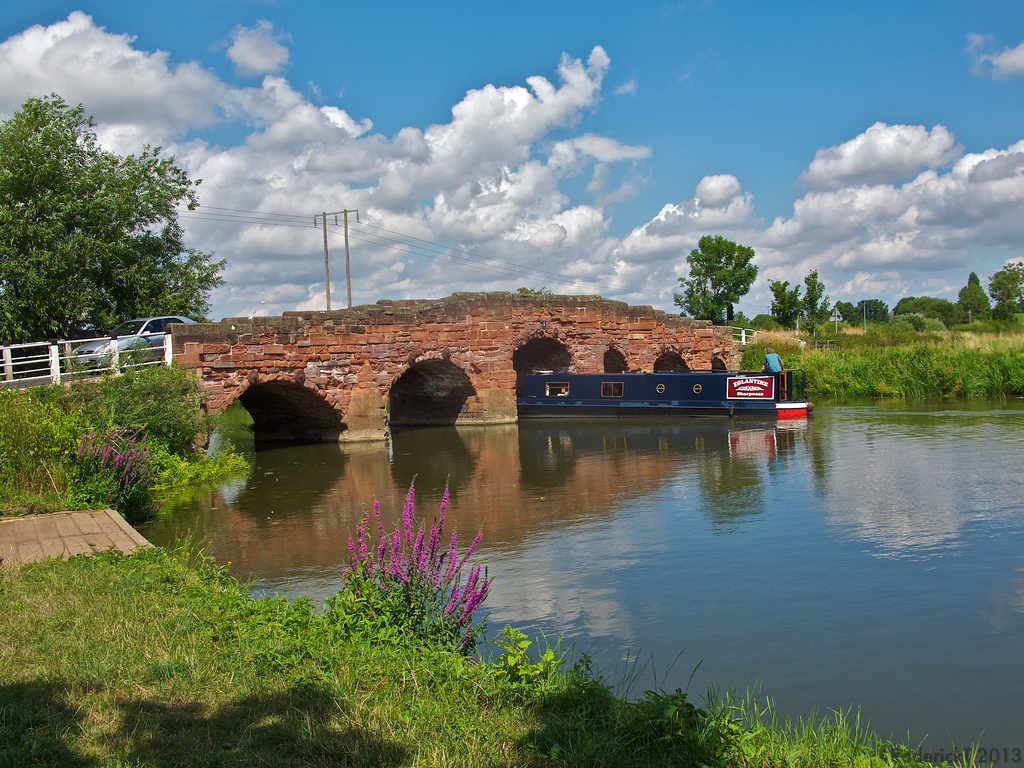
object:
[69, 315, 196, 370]
car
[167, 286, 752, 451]
bridge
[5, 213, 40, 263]
green tree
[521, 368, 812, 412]
boat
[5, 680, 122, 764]
grass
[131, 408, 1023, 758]
river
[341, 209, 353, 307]
telephone poles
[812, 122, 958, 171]
white clouds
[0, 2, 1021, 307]
blue sky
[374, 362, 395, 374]
rocks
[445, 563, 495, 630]
purple plants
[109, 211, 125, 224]
green leaves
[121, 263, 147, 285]
green leaves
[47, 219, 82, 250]
green leaves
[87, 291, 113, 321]
green leaves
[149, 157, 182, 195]
green leaves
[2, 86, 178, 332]
tree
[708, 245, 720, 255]
green leaves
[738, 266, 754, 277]
green leaves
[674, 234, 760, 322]
tree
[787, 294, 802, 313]
green leaves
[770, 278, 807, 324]
tree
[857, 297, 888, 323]
tree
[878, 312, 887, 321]
green leaves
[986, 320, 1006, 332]
green leaves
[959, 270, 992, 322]
tree